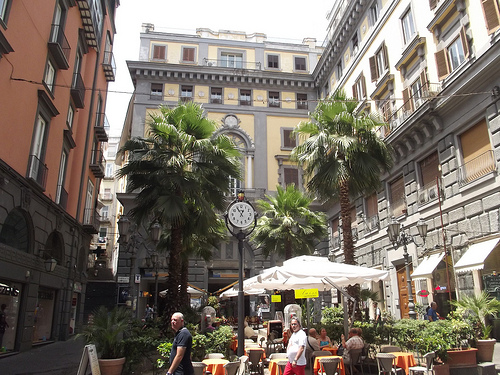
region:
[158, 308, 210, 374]
man walking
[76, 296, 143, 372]
bushy green plant in a brown pot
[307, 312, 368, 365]
people sitting around a table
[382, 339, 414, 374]
orange tablecloth on the table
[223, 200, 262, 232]
clock indicating it is almost 1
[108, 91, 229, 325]
tall tree with large green leaves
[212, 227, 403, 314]
large white umbrella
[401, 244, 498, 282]
two small white awnings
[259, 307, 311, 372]
woman in a white shirt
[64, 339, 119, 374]
sign sitting by the plant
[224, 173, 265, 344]
a clock on a metal pole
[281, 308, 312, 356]
a man wearing a white shirt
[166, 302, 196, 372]
a man wearing a black shirt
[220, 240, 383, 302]
white outdoor umbrellas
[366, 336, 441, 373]
a table with a orange tablecloth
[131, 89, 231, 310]
two tall palm trees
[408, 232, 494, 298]
two white awnings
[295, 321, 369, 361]
four people sitting at a table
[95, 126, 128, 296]
a building with balconies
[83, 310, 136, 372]
a large potted plant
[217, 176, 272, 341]
The clock is on a pole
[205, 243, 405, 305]
The umbrella is white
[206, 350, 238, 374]
White and red table cloth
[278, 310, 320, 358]
Woman wearing white shirt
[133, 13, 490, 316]
Large yellow and grey building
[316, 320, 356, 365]
The people are sitting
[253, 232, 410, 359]
The people are under the umbrella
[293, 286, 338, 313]
The sign is yellow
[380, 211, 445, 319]
The light post is black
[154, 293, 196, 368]
Man wearing a black shirt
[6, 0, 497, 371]
two buildings in close proximity to each other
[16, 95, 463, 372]
open area between buildings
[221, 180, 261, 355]
large clock in open area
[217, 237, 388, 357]
large stationary umbrellas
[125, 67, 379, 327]
palm trees of varying heights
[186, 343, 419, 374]
tables covered with orange cloths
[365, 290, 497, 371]
large potted plants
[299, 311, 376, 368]
people sitting around a small circular table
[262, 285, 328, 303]
bright yellow signs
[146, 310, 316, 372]
man and woman walking to the left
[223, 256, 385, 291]
a white patio umbrella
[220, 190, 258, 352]
a white outdoor clock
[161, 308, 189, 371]
a pedestrian walking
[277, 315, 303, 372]
a pedestrian walking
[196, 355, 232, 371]
a table with orange tablecloth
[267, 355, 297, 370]
a table with orange tablecloth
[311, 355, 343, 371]
a table with orange tablecloth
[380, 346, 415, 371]
a table with orange tablecloth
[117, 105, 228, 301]
a tall green palm tree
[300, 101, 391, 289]
a tall green palm tree